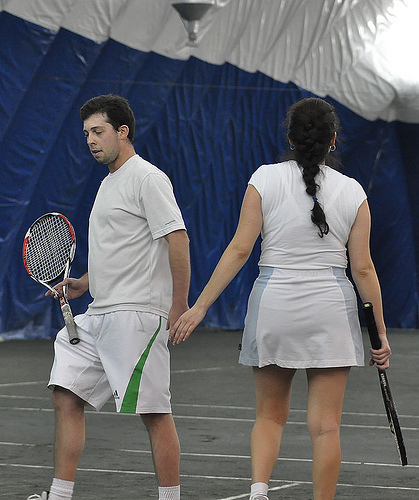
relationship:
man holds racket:
[39, 88, 221, 386] [4, 193, 91, 340]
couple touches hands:
[27, 93, 390, 498] [165, 302, 207, 343]